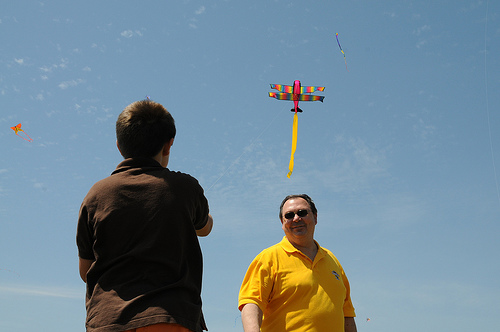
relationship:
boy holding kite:
[70, 95, 233, 332] [260, 71, 337, 183]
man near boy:
[236, 187, 380, 331] [70, 95, 233, 332]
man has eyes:
[236, 187, 380, 331] [282, 209, 308, 219]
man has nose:
[236, 187, 380, 331] [290, 214, 303, 224]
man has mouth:
[236, 187, 380, 331] [290, 223, 307, 231]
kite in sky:
[260, 71, 337, 183] [0, 0, 499, 331]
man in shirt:
[236, 187, 380, 331] [235, 237, 359, 330]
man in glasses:
[236, 187, 380, 331] [281, 207, 312, 219]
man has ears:
[236, 187, 380, 331] [279, 212, 322, 223]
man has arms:
[236, 187, 380, 331] [232, 266, 362, 331]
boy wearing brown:
[70, 95, 233, 332] [58, 168, 220, 331]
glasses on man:
[281, 207, 312, 219] [236, 187, 380, 331]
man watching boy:
[236, 187, 380, 331] [70, 95, 233, 332]